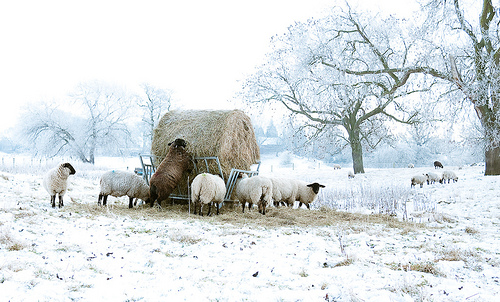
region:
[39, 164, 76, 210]
sheep is next to sheep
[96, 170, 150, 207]
sheep is next to sheep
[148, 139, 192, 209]
sheep is next to sheep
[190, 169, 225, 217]
sheep is next to sheep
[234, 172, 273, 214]
sheep is next to sheep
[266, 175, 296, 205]
sheep is next to sheep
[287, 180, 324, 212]
sheep is next to sheep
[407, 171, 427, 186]
sheep is next to sheep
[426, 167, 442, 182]
sheep is next to sheep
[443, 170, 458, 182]
sheep is next to sheep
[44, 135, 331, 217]
Sheep gathered around a bale of hay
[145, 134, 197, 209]
Brown sheep leaning on bale of hay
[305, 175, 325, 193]
Sheep with black face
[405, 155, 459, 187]
Sheep in the distance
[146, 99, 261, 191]
A bale of hay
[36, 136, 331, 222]
Sheep standing in the snow covered area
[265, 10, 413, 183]
Tree with snow on it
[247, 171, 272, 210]
A sheep's rear end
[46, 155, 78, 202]
Sheep with its head turned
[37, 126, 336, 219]
White sheep standing in white snow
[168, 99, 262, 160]
large round of straw in photo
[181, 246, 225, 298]
patch of snow in front of photo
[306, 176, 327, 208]
sheep with black face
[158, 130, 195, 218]
dark brown sheep standing while eating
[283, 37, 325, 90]
bare tree branches with snow on it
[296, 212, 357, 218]
hay dropped on the ground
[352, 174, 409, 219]
tall frozen weeds in distance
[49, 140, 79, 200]
sheep facing right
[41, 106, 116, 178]
tree shaped like letter v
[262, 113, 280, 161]
building off in the distance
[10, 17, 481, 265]
The sheep are out in the snow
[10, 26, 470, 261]
The sheep are looking for food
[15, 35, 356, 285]
The sheep are all close together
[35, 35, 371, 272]
The sheep are on the frozen ground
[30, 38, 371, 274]
The sheep are out in the winter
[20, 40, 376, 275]
The sheep are male and female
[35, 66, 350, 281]
One of the sheep is colored differently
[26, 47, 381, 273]
The sheep are having a good time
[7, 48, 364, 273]
The sheep belong to a farmer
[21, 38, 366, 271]
The sheep are watching for danger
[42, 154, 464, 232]
Herd of sheep outside.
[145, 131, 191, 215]
Brown sheep in the herd.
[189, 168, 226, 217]
white sheep in the herd.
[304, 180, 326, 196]
Black face on the sheep.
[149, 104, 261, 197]
Roll of hay on the ground.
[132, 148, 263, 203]
Metal bars around the hay.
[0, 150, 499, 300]
White snow on the ground.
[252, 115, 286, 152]
building in the background.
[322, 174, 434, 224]
Weeds on the ground.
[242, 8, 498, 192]
Trees by the sheep.